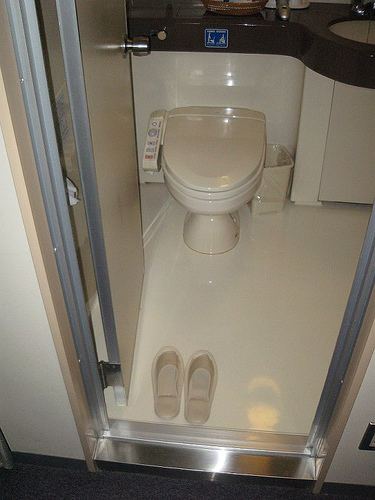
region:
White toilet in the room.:
[141, 95, 276, 264]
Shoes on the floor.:
[148, 345, 221, 424]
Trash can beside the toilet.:
[250, 118, 294, 216]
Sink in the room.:
[319, 1, 372, 57]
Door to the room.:
[33, 0, 147, 413]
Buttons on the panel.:
[140, 108, 167, 173]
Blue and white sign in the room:
[199, 23, 231, 50]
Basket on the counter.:
[198, 0, 270, 19]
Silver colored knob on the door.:
[113, 25, 153, 65]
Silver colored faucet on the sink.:
[350, 0, 367, 17]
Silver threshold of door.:
[101, 419, 323, 479]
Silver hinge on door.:
[92, 353, 125, 395]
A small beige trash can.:
[251, 137, 290, 216]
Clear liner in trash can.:
[252, 139, 287, 202]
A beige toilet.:
[144, 95, 266, 256]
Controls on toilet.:
[143, 99, 163, 175]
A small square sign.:
[201, 26, 230, 49]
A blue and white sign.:
[202, 26, 230, 49]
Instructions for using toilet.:
[204, 26, 229, 48]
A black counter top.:
[139, 0, 374, 83]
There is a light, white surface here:
[271, 304, 286, 368]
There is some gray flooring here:
[37, 476, 43, 497]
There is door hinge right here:
[94, 345, 128, 395]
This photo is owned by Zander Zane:
[52, 276, 145, 459]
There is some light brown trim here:
[45, 302, 78, 386]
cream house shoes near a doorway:
[148, 329, 223, 490]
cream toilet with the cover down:
[141, 78, 269, 261]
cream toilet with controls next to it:
[141, 90, 269, 261]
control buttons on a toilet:
[139, 103, 191, 191]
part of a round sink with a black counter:
[331, 4, 373, 52]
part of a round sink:
[325, 6, 374, 77]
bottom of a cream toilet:
[167, 200, 255, 256]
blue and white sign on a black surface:
[185, 24, 232, 53]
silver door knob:
[99, 13, 159, 69]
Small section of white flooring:
[277, 208, 300, 236]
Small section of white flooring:
[299, 204, 324, 229]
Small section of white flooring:
[321, 204, 361, 234]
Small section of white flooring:
[308, 237, 346, 278]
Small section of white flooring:
[251, 234, 276, 256]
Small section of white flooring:
[279, 271, 321, 305]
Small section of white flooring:
[280, 306, 315, 336]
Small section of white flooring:
[276, 346, 302, 378]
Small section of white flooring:
[237, 399, 297, 429]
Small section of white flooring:
[167, 299, 243, 335]